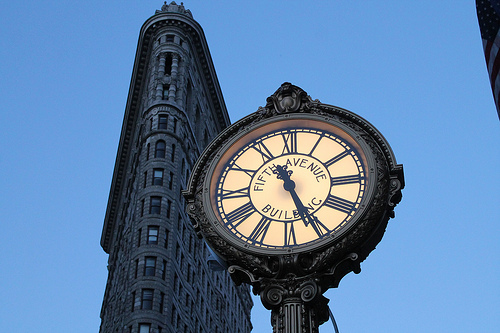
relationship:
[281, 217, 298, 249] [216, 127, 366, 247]
roman numeral on clock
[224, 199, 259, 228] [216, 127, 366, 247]
numerals on clock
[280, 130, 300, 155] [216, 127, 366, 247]
roman numeral on clock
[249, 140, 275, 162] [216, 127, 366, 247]
roman numeral on clock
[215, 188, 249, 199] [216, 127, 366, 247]
roman numeral on clock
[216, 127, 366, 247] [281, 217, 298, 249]
clock has a roman numeral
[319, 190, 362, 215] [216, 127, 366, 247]
roman numeral on a clock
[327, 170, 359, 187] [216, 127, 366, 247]
roman numeral on a clock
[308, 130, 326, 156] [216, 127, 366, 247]
roman numerals on a clock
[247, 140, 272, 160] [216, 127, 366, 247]
roman numeral on a clock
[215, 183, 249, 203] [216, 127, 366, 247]
roman numeral on a clock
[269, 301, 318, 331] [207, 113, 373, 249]
post under clock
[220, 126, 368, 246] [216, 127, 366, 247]
roman numerals on clock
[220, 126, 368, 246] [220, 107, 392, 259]
roman numerals on clock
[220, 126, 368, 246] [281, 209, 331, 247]
roman numerals on clock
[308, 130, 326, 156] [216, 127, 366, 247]
roman numerals on clock